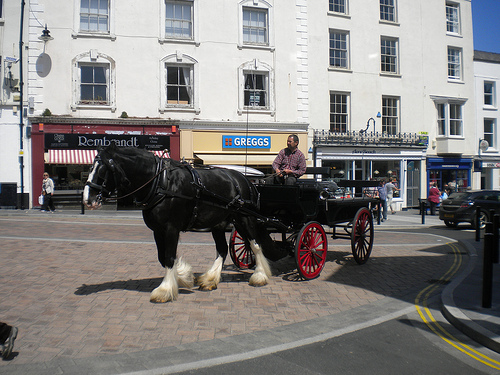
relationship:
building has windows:
[66, 7, 417, 159] [69, 51, 280, 115]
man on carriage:
[269, 132, 309, 184] [255, 178, 382, 237]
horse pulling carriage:
[68, 145, 265, 243] [255, 178, 382, 237]